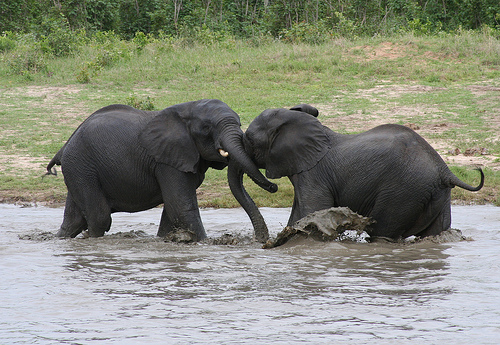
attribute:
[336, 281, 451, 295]
wave — part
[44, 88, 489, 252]
elephants — young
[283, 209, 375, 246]
splash — part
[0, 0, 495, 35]
bushes — green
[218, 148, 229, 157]
elephant's tusk — white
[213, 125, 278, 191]
trunk — part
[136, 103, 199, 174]
ear — large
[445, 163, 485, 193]
tail — small